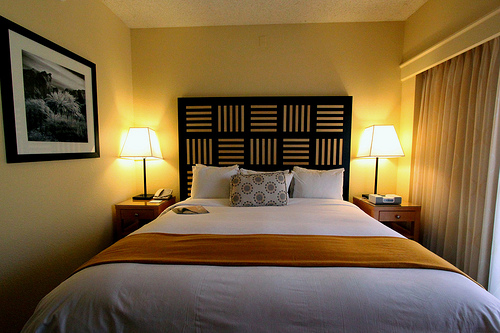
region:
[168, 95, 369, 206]
black headboard for bed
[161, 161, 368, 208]
white pillows on bed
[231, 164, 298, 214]
grey pillow on bed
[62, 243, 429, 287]
orange sheet on bed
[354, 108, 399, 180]
white lampshade near bed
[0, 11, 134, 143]
black frame on picture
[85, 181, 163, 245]
brown table near bed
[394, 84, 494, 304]
brown curtains on window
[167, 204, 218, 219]
book lying on bed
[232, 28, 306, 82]
yellow wall behind bed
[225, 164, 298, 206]
Fancy colorful bed pillow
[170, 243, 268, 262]
Part of gold bed quilt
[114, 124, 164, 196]
Illuminated white table lamp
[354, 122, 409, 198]
Illuminated white table lamp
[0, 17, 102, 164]
Large picture frame on wall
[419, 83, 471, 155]
Part of floor length drape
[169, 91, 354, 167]
Ornate dark bed headboard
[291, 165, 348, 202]
White fluffy bed pillow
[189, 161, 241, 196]
White fluffy bed pillow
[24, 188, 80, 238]
)Part of gold wall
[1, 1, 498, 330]
A bedroom is very clean and neat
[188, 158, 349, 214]
Pillows on a bed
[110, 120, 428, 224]
Two lamps on two end tables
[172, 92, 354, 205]
The headboard pattern is unique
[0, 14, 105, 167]
A big framed photograph is on the wall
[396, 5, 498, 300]
The blinds are vertical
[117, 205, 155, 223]
A brown wooden drawer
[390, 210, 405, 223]
A knob on a drawer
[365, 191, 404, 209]
A box of tissues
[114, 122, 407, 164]
Two lights are turned on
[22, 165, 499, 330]
the bed is made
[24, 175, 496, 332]
two small tables on either side of the bed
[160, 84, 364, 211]
large headboard against the wall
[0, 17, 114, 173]
artwork hanging on the wall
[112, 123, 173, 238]
lamp on the table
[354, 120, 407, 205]
lamp is turned on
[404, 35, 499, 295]
curtains on the window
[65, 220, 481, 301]
gold blanket laying across the bed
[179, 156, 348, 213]
pillows propped up on the bed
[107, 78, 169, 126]
light shining on the wall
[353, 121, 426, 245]
A lamp on an end table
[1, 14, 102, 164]
A framed black and white photo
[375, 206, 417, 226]
A brown wooden drawer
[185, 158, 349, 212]
Pillows are on the bed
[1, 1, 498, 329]
The walls are pale yellow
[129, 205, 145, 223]
A knob on a drawer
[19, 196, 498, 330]
White bedsheets on the bed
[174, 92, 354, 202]
The headboard is black